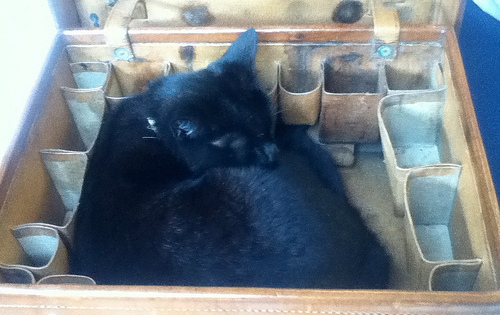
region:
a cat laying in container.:
[66, 27, 394, 284]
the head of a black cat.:
[160, 14, 287, 170]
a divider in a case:
[364, 103, 451, 174]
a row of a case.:
[1, 57, 111, 284]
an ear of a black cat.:
[211, 25, 283, 105]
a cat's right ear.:
[161, 96, 212, 152]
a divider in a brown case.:
[376, 105, 461, 173]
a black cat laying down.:
[203, 127, 394, 288]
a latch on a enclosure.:
[364, 0, 402, 65]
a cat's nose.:
[261, 131, 288, 176]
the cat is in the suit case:
[114, 30, 389, 290]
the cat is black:
[85, 28, 387, 290]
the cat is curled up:
[79, 23, 393, 288]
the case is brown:
[0, 2, 499, 310]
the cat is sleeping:
[89, 29, 394, 282]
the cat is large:
[73, 30, 392, 283]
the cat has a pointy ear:
[216, 27, 256, 75]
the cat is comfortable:
[76, 30, 394, 285]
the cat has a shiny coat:
[77, 26, 394, 288]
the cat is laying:
[79, 28, 392, 285]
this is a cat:
[129, 77, 301, 293]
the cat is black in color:
[190, 175, 293, 257]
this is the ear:
[229, 30, 261, 65]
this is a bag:
[367, 35, 473, 205]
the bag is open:
[345, 12, 432, 105]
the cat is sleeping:
[151, 87, 286, 204]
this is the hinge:
[365, 2, 406, 61]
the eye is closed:
[215, 130, 240, 147]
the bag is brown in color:
[410, 92, 477, 181]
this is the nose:
[264, 147, 284, 163]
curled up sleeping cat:
[80, 26, 385, 284]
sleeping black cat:
[89, 27, 386, 293]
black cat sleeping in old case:
[19, 1, 446, 287]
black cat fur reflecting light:
[203, 172, 328, 276]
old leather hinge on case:
[53, 1, 194, 68]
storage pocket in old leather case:
[363, 36, 497, 279]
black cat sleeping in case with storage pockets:
[27, 16, 388, 283]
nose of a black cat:
[250, 133, 285, 171]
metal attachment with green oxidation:
[368, 37, 403, 67]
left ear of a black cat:
[213, 23, 270, 86]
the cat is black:
[107, 67, 301, 248]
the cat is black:
[147, 101, 308, 308]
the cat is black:
[147, 55, 282, 196]